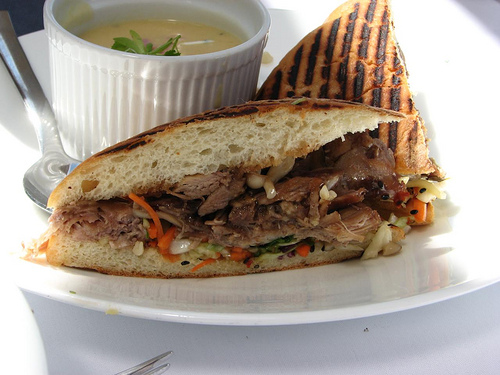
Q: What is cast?
A: Shadow.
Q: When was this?
A: Daytime.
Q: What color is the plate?
A: White.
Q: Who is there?
A: No one.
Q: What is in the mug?
A: Tea.